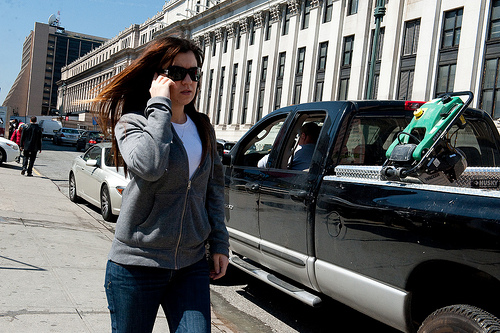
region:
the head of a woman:
[128, 37, 231, 139]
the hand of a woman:
[143, 61, 176, 113]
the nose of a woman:
[175, 71, 198, 92]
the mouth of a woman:
[178, 86, 199, 118]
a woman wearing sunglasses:
[149, 32, 238, 98]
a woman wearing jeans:
[89, 225, 264, 318]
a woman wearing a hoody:
[78, 23, 269, 275]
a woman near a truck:
[89, 85, 343, 268]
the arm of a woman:
[84, 39, 230, 204]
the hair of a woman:
[84, 1, 250, 120]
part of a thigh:
[172, 286, 194, 308]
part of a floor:
[18, 269, 38, 297]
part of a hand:
[210, 253, 235, 292]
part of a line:
[53, 257, 78, 302]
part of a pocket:
[160, 217, 172, 254]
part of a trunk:
[362, 228, 407, 286]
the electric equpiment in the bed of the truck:
[374, 88, 486, 183]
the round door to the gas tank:
[321, 206, 357, 239]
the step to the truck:
[231, 248, 322, 322]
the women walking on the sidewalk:
[81, 21, 244, 331]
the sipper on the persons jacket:
[168, 173, 195, 275]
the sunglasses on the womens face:
[157, 57, 202, 86]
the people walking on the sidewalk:
[9, 107, 52, 187]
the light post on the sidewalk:
[361, 0, 395, 96]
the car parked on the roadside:
[60, 130, 126, 223]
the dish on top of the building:
[39, 5, 71, 32]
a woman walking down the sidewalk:
[86, 32, 238, 330]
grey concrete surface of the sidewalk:
[38, 245, 83, 328]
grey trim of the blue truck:
[261, 236, 386, 312]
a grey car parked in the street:
[64, 136, 142, 220]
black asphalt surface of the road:
[41, 150, 67, 175]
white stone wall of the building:
[270, 19, 352, 49]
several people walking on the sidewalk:
[3, 114, 50, 177]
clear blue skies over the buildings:
[81, 3, 128, 26]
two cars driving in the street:
[54, 123, 106, 150]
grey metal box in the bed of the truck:
[333, 163, 498, 188]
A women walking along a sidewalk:
[90, 35, 230, 331]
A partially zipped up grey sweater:
[108, 95, 230, 271]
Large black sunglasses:
[150, 66, 200, 81]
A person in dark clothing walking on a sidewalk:
[19, 115, 44, 177]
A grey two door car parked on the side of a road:
[67, 140, 134, 221]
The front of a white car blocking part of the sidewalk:
[0, 135, 21, 167]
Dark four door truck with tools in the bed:
[220, 90, 497, 331]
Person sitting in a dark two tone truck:
[256, 121, 318, 173]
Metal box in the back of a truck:
[332, 165, 498, 187]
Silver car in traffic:
[52, 126, 82, 146]